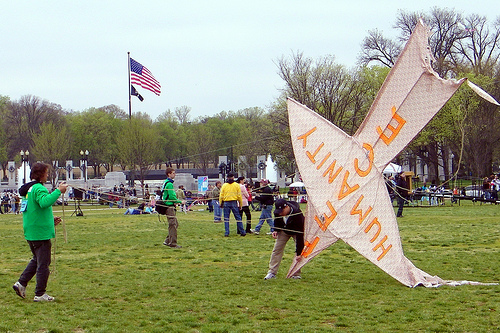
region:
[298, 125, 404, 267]
orange lettering on kite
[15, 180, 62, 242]
girl in green jacket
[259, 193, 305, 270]
man bending down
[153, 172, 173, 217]
person carring case on shoulder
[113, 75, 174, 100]
two flags flying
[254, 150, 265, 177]
wreath on building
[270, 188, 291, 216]
man wearing a black hat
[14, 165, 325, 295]
woman holding string to kite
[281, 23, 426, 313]
kite on the ground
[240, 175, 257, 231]
person in pink sweater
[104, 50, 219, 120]
a flag of USA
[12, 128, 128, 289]
woman holding kite threads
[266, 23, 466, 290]
Large white kite on the ground.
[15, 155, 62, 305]
Woman in a green jacket.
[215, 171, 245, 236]
Person in a yellow jacket.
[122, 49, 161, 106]
flags on the flag pole.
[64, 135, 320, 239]
White kite string.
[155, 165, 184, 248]
Person with black bag.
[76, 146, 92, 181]
Light pole in the background.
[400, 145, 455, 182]
Structure in the background.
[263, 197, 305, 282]
Man wearing black jacket.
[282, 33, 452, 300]
Orange letters on the kite.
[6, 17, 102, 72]
a clear light blue sky.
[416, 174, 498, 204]
a bunch of people are standing in the park.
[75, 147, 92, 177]
a black and white light pole.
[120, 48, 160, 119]
a american red white and blue flag.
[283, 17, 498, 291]
a big huge beige and orange kite.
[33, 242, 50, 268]
a woman is wearing grey pants.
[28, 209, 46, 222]
a woman is wearing a green jacket.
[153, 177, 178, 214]
a man is carrying a black shoulder bag.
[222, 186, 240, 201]
a man is wearing a yellow jacket.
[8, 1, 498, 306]
a man and woman are flying a big kite.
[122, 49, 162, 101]
US flag flying over a dark blue flag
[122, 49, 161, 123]
gray flagpole with two flags on it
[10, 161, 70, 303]
woman with gray pants and green jacket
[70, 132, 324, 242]
strings to a white and orange kite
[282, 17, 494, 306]
large orange and white kite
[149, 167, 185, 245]
man standing with black bag with a strap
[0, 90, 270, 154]
tops of mostly green trees in the background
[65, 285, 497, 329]
green grassy area where people are flying a kite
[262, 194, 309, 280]
man with tan pants and a blue sweatshirt bending over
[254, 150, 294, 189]
white structure in the background